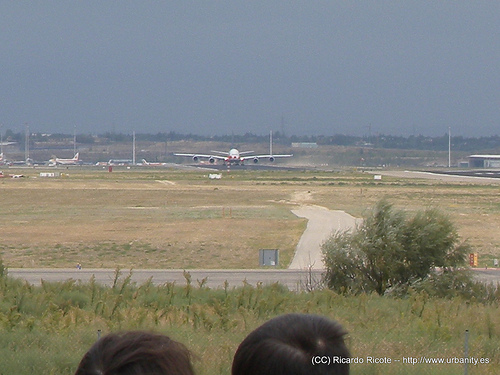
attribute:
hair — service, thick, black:
[238, 306, 347, 374]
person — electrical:
[78, 327, 190, 375]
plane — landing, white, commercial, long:
[174, 142, 286, 173]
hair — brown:
[75, 329, 196, 365]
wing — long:
[173, 143, 225, 167]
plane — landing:
[172, 148, 295, 169]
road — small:
[284, 187, 364, 271]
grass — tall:
[0, 283, 484, 373]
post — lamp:
[444, 122, 454, 170]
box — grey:
[255, 245, 281, 267]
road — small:
[4, 263, 484, 293]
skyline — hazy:
[0, 0, 484, 151]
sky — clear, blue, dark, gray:
[1, 0, 483, 134]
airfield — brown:
[1, 174, 294, 268]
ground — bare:
[0, 172, 290, 263]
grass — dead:
[2, 177, 291, 267]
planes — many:
[2, 139, 297, 175]